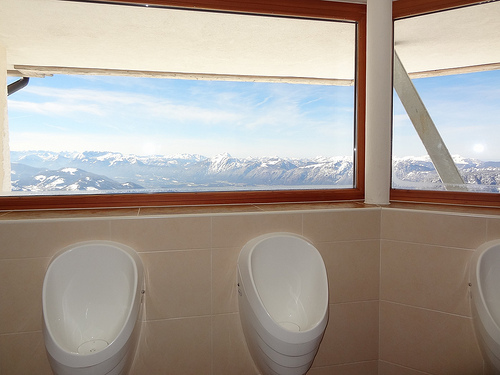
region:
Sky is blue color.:
[77, 69, 332, 118]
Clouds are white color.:
[25, 113, 284, 150]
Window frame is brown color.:
[23, 26, 375, 221]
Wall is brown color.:
[331, 229, 458, 359]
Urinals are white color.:
[22, 255, 492, 373]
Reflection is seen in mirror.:
[21, 91, 336, 187]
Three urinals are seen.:
[40, 237, 499, 357]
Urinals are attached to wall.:
[6, 233, 489, 349]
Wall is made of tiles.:
[143, 243, 234, 336]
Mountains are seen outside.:
[46, 143, 340, 185]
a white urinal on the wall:
[239, 228, 346, 373]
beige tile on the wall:
[394, 221, 460, 373]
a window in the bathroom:
[40, 74, 354, 191]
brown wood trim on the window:
[71, 194, 357, 207]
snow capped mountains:
[67, 146, 337, 179]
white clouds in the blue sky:
[65, 85, 273, 134]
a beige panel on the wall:
[366, 6, 392, 207]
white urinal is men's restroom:
[46, 241, 496, 360]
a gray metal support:
[8, 77, 32, 92]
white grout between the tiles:
[394, 299, 433, 310]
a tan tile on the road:
[299, 206, 381, 244]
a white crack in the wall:
[134, 241, 202, 260]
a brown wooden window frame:
[0, 0, 367, 215]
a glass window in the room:
[1, 0, 357, 197]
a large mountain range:
[7, 144, 353, 194]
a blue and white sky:
[6, 73, 356, 160]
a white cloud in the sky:
[5, 99, 105, 126]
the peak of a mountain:
[220, 148, 235, 160]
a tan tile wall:
[1, 203, 381, 373]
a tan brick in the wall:
[379, 238, 480, 321]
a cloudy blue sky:
[7, 71, 352, 158]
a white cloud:
[9, 97, 96, 121]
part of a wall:
[347, 217, 374, 254]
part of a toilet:
[246, 290, 286, 326]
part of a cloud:
[216, 82, 264, 130]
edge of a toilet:
[274, 316, 304, 339]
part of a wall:
[167, 290, 224, 369]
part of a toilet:
[267, 265, 299, 307]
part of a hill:
[237, 130, 273, 179]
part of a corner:
[362, 297, 384, 347]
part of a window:
[179, 100, 218, 142]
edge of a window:
[343, 137, 371, 182]